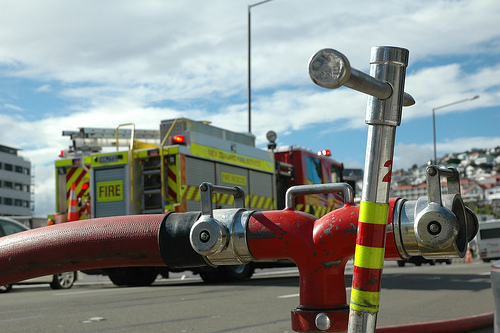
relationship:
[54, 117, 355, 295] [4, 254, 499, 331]
fire truck on street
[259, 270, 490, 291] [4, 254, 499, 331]
shadow on street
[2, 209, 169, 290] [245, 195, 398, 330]
fire hose connected to water supplly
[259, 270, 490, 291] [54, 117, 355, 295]
shadow of fire truck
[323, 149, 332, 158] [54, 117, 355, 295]
light on fire truck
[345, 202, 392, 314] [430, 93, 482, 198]
tape on pole